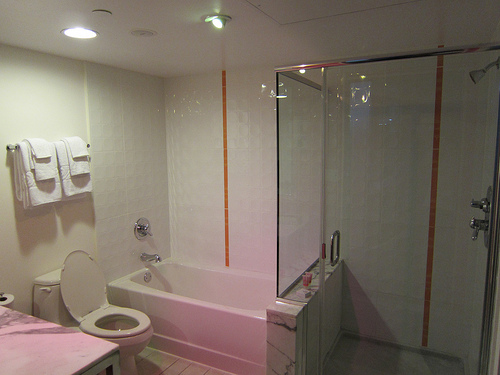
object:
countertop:
[0, 308, 118, 373]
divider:
[274, 69, 320, 299]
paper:
[0, 293, 14, 307]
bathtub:
[105, 256, 278, 375]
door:
[317, 48, 490, 374]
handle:
[326, 229, 341, 267]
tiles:
[173, 76, 237, 90]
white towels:
[6, 134, 91, 211]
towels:
[12, 135, 92, 209]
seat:
[78, 304, 150, 337]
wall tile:
[264, 304, 299, 373]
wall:
[1, 44, 171, 321]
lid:
[59, 249, 108, 323]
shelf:
[279, 255, 338, 303]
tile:
[229, 245, 274, 269]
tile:
[229, 190, 254, 231]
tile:
[173, 170, 210, 190]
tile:
[197, 147, 222, 174]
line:
[221, 66, 230, 266]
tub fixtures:
[138, 250, 159, 264]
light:
[60, 27, 99, 39]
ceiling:
[0, 0, 498, 78]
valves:
[468, 195, 498, 239]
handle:
[133, 217, 154, 239]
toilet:
[33, 251, 155, 375]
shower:
[468, 61, 498, 84]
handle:
[39, 286, 50, 293]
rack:
[7, 137, 89, 149]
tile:
[329, 334, 362, 364]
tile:
[374, 339, 400, 373]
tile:
[133, 348, 210, 373]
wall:
[162, 42, 484, 360]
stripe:
[420, 41, 438, 349]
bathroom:
[0, 0, 500, 375]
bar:
[6, 145, 90, 151]